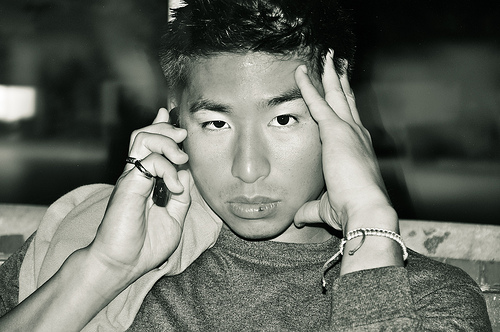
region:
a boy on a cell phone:
[16, 14, 487, 329]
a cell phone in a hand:
[148, 106, 186, 206]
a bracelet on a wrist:
[335, 226, 417, 260]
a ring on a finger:
[133, 156, 154, 195]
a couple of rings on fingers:
[123, 153, 153, 180]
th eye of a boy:
[262, 107, 304, 134]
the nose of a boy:
[233, 135, 271, 185]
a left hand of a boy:
[285, 51, 409, 228]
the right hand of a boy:
[91, 98, 193, 278]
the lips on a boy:
[216, 190, 285, 224]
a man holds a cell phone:
[12, 5, 484, 330]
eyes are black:
[196, 109, 304, 136]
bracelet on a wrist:
[316, 210, 416, 280]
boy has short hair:
[118, 0, 398, 295]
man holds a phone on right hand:
[5, 8, 474, 328]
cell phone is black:
[147, 97, 185, 206]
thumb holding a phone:
[163, 165, 195, 232]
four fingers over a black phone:
[121, 103, 190, 201]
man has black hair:
[82, 5, 426, 280]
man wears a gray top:
[3, 5, 490, 330]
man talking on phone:
[55, 15, 401, 278]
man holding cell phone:
[50, 28, 416, 258]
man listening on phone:
[89, 32, 386, 251]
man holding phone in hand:
[64, 64, 295, 291]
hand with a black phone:
[120, 95, 207, 225]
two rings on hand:
[100, 99, 198, 261]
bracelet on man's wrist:
[308, 215, 418, 280]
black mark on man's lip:
[253, 205, 271, 216]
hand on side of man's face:
[213, 33, 388, 280]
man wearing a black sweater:
[6, 234, 465, 329]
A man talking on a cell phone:
[6, 11, 498, 326]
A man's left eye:
[258, 105, 308, 135]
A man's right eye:
[186, 112, 228, 132]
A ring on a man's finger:
[131, 155, 151, 180]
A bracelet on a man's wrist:
[297, 220, 419, 285]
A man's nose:
[225, 122, 272, 182]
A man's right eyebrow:
[185, 90, 235, 115]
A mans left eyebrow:
[261, 85, 303, 111]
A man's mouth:
[219, 187, 294, 223]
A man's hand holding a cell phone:
[87, 94, 198, 275]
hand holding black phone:
[90, 100, 205, 269]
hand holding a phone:
[85, 73, 250, 272]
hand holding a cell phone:
[89, 90, 196, 260]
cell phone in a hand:
[55, 99, 220, 259]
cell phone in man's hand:
[98, 98, 202, 268]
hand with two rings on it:
[92, 94, 194, 251]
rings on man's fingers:
[88, 116, 190, 210]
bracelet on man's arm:
[270, 202, 430, 280]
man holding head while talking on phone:
[103, 30, 400, 231]